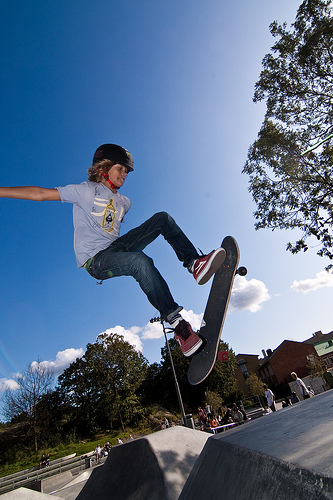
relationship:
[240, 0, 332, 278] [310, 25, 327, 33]
tree with green leaves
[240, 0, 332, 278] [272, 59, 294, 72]
tree with green leaves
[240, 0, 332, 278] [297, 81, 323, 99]
tree with green leaves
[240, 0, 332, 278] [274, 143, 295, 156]
tree with green leaves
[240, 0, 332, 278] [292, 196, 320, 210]
tree with green leaves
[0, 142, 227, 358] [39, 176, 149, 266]
boy wearing shirt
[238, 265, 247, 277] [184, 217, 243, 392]
wheel on skate board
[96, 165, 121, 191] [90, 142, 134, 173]
chin strap on helmet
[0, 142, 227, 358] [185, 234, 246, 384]
boy on skate board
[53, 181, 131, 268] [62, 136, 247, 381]
blue teeshirt on person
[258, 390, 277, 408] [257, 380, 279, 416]
shirt on person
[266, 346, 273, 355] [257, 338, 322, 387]
chimney on building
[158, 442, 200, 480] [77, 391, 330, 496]
shadow on ramp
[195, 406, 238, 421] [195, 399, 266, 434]
people on bleachers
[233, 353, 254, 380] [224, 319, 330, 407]
window on building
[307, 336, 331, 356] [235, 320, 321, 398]
roof on building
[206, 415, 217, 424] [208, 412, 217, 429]
orange shirt on person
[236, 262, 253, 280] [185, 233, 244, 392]
wheel on skateboard